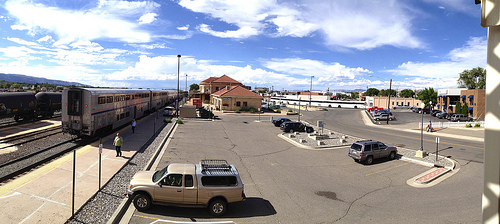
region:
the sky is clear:
[140, 6, 314, 100]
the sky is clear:
[76, 8, 198, 78]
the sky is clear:
[82, 8, 238, 127]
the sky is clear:
[84, 12, 129, 58]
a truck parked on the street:
[128, 93, 232, 221]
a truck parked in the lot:
[111, 138, 228, 218]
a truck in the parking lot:
[101, 129, 239, 221]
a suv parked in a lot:
[300, 95, 444, 218]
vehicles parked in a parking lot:
[150, 66, 483, 223]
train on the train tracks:
[14, 41, 282, 194]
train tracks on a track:
[4, 28, 336, 195]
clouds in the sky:
[202, 14, 462, 76]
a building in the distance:
[176, 30, 318, 152]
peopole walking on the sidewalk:
[75, 60, 282, 191]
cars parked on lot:
[187, 70, 437, 222]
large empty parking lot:
[191, 82, 399, 219]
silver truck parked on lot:
[125, 145, 240, 219]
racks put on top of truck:
[157, 151, 264, 198]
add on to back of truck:
[150, 162, 255, 210]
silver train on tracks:
[27, 87, 191, 162]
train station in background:
[205, 70, 282, 125]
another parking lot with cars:
[365, 80, 426, 127]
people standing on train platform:
[101, 100, 148, 170]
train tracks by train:
[18, 114, 70, 182]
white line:
[32, 194, 50, 206]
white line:
[7, 188, 62, 216]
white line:
[22, 190, 56, 211]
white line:
[25, 212, 43, 222]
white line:
[37, 184, 65, 216]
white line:
[47, 195, 71, 209]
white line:
[22, 182, 70, 220]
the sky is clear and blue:
[101, 13, 248, 85]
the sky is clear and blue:
[93, 23, 223, 63]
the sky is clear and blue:
[114, 18, 314, 120]